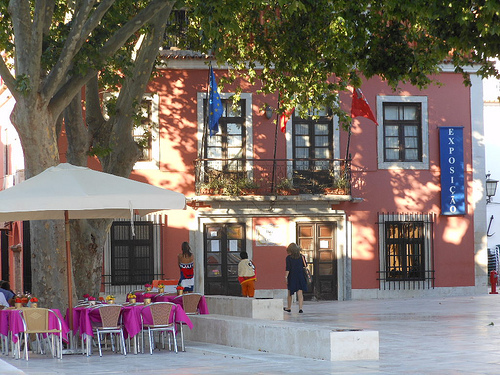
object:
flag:
[350, 85, 379, 125]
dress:
[285, 252, 310, 291]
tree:
[0, 0, 498, 350]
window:
[384, 125, 399, 136]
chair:
[139, 301, 181, 354]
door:
[293, 221, 338, 300]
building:
[0, 0, 488, 299]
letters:
[448, 204, 456, 213]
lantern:
[485, 179, 497, 204]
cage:
[377, 211, 437, 289]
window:
[385, 242, 399, 255]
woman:
[237, 248, 257, 298]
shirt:
[235, 259, 255, 277]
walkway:
[0, 287, 499, 374]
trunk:
[9, 103, 80, 321]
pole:
[197, 62, 214, 184]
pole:
[343, 114, 352, 164]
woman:
[283, 241, 308, 313]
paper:
[209, 238, 219, 251]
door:
[203, 223, 246, 296]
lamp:
[485, 179, 499, 206]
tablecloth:
[80, 304, 142, 334]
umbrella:
[1, 161, 186, 350]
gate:
[378, 213, 435, 291]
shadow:
[356, 312, 475, 326]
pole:
[64, 211, 73, 352]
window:
[294, 124, 309, 135]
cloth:
[44, 307, 66, 339]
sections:
[315, 136, 330, 146]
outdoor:
[0, 0, 499, 374]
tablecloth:
[1, 306, 71, 343]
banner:
[423, 117, 483, 217]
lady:
[177, 241, 195, 295]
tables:
[80, 304, 181, 355]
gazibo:
[0, 162, 190, 223]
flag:
[207, 65, 225, 138]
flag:
[278, 89, 296, 133]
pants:
[239, 275, 255, 296]